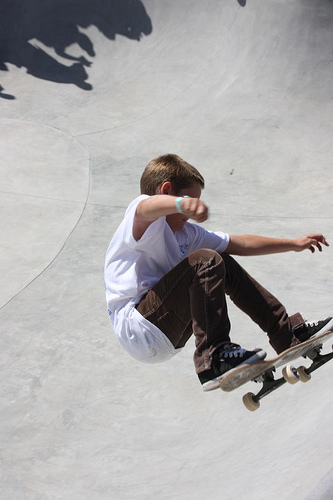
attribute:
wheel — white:
[291, 366, 313, 386]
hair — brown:
[140, 153, 204, 195]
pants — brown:
[99, 245, 330, 378]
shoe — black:
[194, 336, 268, 403]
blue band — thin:
[169, 192, 194, 223]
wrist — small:
[283, 230, 305, 257]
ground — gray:
[2, 1, 330, 498]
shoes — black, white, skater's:
[188, 349, 267, 376]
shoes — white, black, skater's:
[291, 321, 329, 337]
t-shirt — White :
[101, 203, 198, 319]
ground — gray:
[0, 263, 325, 498]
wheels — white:
[240, 345, 332, 411]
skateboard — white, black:
[221, 329, 331, 411]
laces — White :
[220, 349, 246, 359]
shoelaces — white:
[217, 345, 249, 359]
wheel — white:
[242, 382, 263, 411]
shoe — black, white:
[266, 318, 331, 341]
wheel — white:
[245, 392, 258, 410]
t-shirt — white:
[98, 193, 228, 365]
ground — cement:
[5, 349, 324, 495]